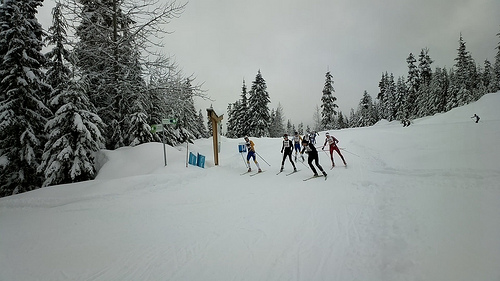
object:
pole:
[161, 118, 166, 166]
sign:
[151, 118, 177, 166]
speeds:
[237, 132, 407, 186]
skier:
[301, 140, 327, 177]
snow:
[213, 168, 225, 177]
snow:
[183, 221, 216, 238]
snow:
[59, 264, 98, 280]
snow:
[171, 274, 189, 280]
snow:
[226, 153, 234, 163]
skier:
[322, 132, 347, 167]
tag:
[266, 146, 326, 166]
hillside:
[0, 89, 500, 281]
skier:
[241, 134, 263, 176]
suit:
[245, 139, 260, 169]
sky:
[172, 20, 261, 52]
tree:
[245, 68, 271, 138]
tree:
[236, 78, 249, 136]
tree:
[321, 65, 340, 130]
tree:
[453, 32, 476, 101]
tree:
[381, 71, 397, 122]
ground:
[373, 137, 385, 156]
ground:
[15, 244, 64, 263]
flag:
[238, 144, 248, 168]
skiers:
[280, 134, 297, 172]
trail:
[351, 179, 408, 278]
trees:
[0, 3, 54, 197]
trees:
[35, 78, 102, 188]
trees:
[56, 1, 186, 147]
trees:
[144, 73, 178, 147]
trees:
[268, 102, 286, 138]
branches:
[79, 110, 105, 128]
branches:
[68, 156, 83, 180]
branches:
[51, 132, 73, 149]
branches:
[43, 110, 71, 129]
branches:
[24, 95, 55, 115]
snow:
[401, 247, 493, 274]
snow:
[114, 215, 178, 233]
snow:
[50, 231, 180, 267]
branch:
[127, 50, 142, 57]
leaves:
[62, 156, 69, 161]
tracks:
[368, 148, 392, 175]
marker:
[206, 103, 224, 165]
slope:
[379, 127, 500, 277]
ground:
[241, 190, 366, 273]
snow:
[0, 216, 43, 251]